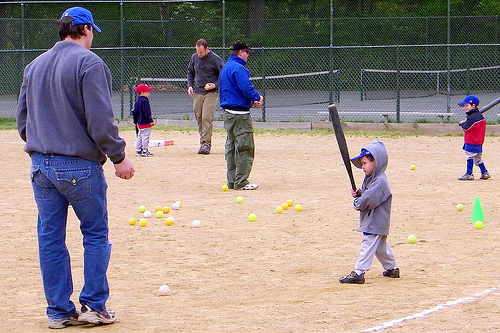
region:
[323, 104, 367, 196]
A black baseball bat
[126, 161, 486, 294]
Tons of yellow and white baseballs on the ground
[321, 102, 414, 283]
A young boy holding a baseball bat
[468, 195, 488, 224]
A light green cone on the ground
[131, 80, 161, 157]
A little boy wearing a red cap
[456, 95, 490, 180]
A young boy wearing red and blue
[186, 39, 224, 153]
A man wearing a gray sweater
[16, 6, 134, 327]
A man wearing a blue cap and a gray sweater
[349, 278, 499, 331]
A white line in the dirt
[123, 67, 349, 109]
A tennis net behind the fence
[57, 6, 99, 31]
A blue baseball cap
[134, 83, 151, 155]
A toddler with a baseball bat in hand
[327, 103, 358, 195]
A small baseball bat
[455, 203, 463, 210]
A baseball on the ground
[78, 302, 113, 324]
An athletic shoe on a right foot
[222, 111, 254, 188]
A pair of cargo pants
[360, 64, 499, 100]
A tennis court net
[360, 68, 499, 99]
A net inside of a tennis court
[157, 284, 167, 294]
A white baseball on the ground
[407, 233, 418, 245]
Baseball that is light green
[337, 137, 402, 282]
little boy dressed in grey holding a baseball bat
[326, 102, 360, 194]
bat the little boy in gray is holding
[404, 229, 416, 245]
yellow ball lying on the ground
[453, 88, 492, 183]
little boy with long blue socks on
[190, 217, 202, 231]
white ball lying on the ground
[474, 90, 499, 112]
bat the little boy in long blue socks is holding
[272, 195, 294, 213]
three balls lined up together on the ground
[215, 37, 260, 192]
man dressed in blue coat and green pants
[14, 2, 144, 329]
man dressed in dark sweat shirt and blue jeans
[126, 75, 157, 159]
little boy in red baseball cap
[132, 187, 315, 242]
the balls are on the ground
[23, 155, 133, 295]
the jeans are blue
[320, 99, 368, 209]
the baseball bat is black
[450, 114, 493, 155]
the jacket is red and black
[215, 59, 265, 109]
the jacket is blue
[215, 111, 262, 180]
the pants are grey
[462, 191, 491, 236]
the cone is green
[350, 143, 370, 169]
the hat is blue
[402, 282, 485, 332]
the line is white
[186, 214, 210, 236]
the ball is white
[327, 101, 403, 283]
Small child with a baseball bat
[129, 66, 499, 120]
Group of nets in the tennis field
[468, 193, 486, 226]
Green cone on the sand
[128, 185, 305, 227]
Group of baseballs on the ground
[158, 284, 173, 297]
White baseball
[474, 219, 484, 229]
Yellow baseball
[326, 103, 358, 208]
Metal bat held by the child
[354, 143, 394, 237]
Gray sweater worn by the child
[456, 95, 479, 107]
Blue hat worn by the child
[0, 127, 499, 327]
Baseball playing field